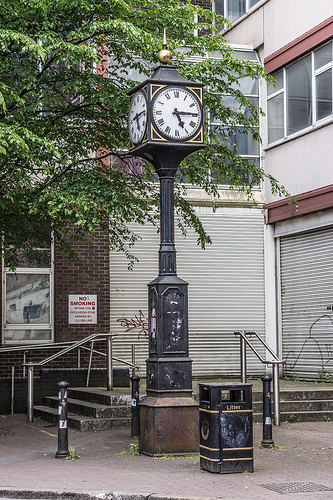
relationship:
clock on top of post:
[155, 81, 200, 137] [147, 148, 190, 397]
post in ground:
[147, 148, 190, 397] [8, 410, 330, 498]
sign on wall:
[71, 291, 94, 324] [3, 198, 274, 377]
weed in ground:
[127, 439, 137, 458] [8, 410, 330, 498]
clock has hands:
[155, 81, 200, 137] [176, 105, 199, 128]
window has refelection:
[8, 274, 51, 321] [13, 283, 39, 315]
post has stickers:
[147, 148, 190, 397] [149, 315, 156, 336]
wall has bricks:
[3, 198, 274, 377] [79, 240, 97, 248]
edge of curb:
[0, 488, 28, 499] [2, 481, 142, 499]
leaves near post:
[21, 42, 50, 63] [147, 148, 190, 397]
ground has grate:
[8, 410, 330, 498] [264, 479, 331, 496]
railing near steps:
[233, 330, 287, 426] [206, 377, 331, 416]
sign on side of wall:
[71, 291, 94, 324] [3, 198, 274, 377]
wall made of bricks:
[3, 198, 274, 377] [79, 240, 97, 248]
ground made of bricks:
[8, 410, 330, 498] [92, 453, 133, 483]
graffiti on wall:
[119, 309, 151, 334] [3, 198, 274, 377]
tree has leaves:
[1, 2, 299, 271] [21, 42, 50, 63]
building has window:
[1, 5, 332, 407] [8, 274, 51, 321]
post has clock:
[147, 148, 190, 397] [155, 81, 200, 137]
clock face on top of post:
[152, 89, 197, 139] [147, 148, 190, 397]